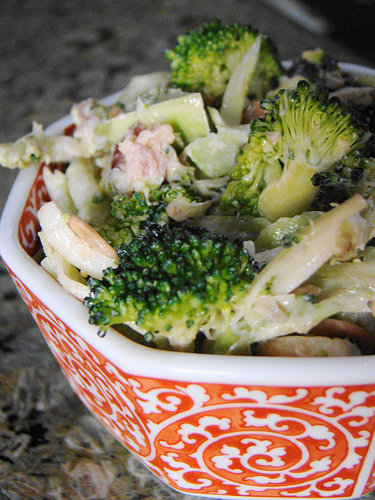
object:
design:
[149, 384, 375, 500]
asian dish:
[0, 15, 374, 356]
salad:
[0, 17, 375, 357]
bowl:
[0, 59, 375, 500]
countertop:
[0, 0, 375, 500]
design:
[18, 165, 53, 257]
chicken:
[117, 123, 175, 193]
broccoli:
[307, 145, 375, 213]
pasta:
[0, 17, 375, 358]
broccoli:
[219, 79, 366, 222]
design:
[41, 122, 78, 173]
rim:
[0, 60, 374, 389]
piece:
[81, 216, 267, 350]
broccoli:
[100, 191, 151, 252]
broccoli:
[160, 16, 285, 123]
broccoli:
[0, 90, 210, 172]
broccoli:
[81, 219, 259, 354]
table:
[0, 0, 375, 500]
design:
[352, 428, 374, 499]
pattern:
[0, 168, 375, 500]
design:
[31, 303, 153, 462]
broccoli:
[93, 181, 199, 254]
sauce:
[324, 243, 375, 324]